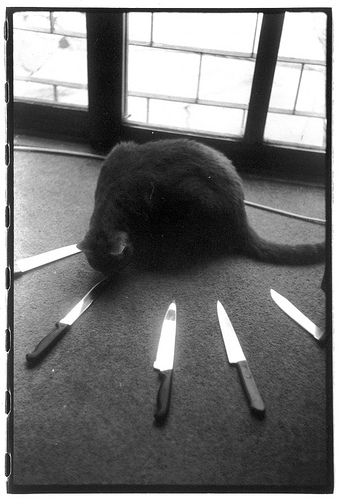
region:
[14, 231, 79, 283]
Long knife pointing at cat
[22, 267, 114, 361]
Knife pointing at cat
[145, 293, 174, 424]
Knife pointing at cat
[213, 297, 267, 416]
Knife pointing at cat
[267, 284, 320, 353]
Knife pointing at cat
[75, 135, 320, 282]
Cat smelling knife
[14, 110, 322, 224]
Long cord behind cat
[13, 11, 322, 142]
Window behind black cat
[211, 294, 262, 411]
Long knife on carpet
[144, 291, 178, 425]
Long knife on carpet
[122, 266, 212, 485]
a knife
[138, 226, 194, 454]
a knife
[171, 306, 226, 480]
a knife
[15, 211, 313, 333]
knives in a circle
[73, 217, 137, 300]
cat smelling a knife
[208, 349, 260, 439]
handle of a knife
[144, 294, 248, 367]
blades on knives on floor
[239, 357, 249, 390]
rivets of knife handle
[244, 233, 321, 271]
tail on the cat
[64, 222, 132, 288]
head of the cat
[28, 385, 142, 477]
floor that the knives are on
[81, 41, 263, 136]
window behind the cat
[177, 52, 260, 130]
pane of the window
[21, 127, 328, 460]
A cat surrounded by knives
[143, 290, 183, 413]
A sharp knife pointing at the cat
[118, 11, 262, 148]
A glass window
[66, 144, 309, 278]
A grey cat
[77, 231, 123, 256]
The cat has two ears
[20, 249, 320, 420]
Five knives on the ground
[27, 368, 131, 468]
Grey carpeting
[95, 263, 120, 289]
The cat's nose is on the knife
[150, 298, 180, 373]
A shining silver blade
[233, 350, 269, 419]
A black knife handle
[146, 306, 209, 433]
a knife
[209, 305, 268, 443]
a knife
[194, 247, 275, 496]
a knife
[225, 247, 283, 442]
a knife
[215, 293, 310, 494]
a knife